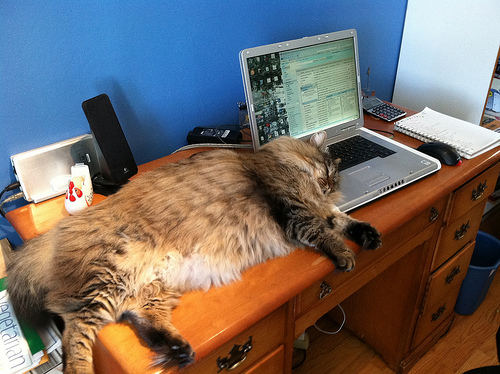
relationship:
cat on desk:
[0, 130, 384, 374] [6, 98, 498, 371]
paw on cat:
[334, 222, 379, 282] [0, 130, 384, 374]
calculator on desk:
[361, 96, 407, 123] [6, 98, 498, 371]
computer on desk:
[238, 27, 442, 218] [6, 98, 498, 371]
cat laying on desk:
[19, 225, 351, 296] [6, 98, 498, 371]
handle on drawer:
[216, 334, 271, 371] [159, 183, 440, 368]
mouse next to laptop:
[414, 122, 484, 169] [221, 27, 493, 248]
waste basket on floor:
[450, 223, 497, 325] [442, 320, 489, 355]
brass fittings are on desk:
[217, 172, 489, 372] [6, 98, 498, 371]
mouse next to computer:
[416, 142, 463, 167] [238, 27, 442, 218]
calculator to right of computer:
[362, 95, 406, 124] [238, 27, 442, 218]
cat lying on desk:
[0, 130, 384, 374] [6, 98, 498, 371]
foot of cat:
[161, 327, 241, 361] [145, 111, 396, 273]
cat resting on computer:
[0, 130, 384, 374] [238, 27, 442, 218]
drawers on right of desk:
[442, 196, 474, 343] [6, 98, 498, 371]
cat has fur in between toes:
[0, 130, 384, 374] [160, 339, 193, 368]